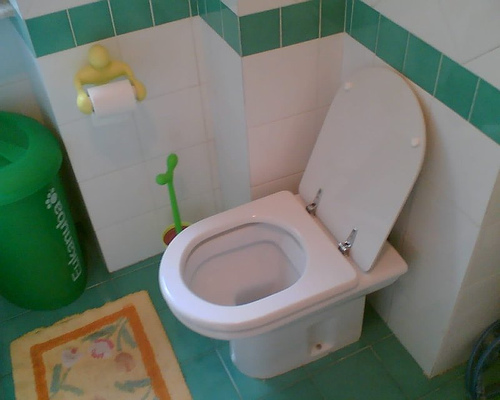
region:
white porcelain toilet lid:
[298, 59, 441, 309]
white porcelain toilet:
[148, 38, 448, 382]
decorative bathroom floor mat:
[2, 285, 184, 395]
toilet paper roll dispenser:
[51, 23, 173, 138]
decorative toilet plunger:
[142, 148, 209, 263]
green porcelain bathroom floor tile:
[293, 331, 400, 398]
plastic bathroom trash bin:
[0, 81, 80, 319]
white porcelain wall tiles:
[138, 25, 231, 138]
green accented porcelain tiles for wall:
[186, 0, 408, 62]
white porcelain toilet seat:
[151, 173, 351, 323]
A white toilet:
[156, 65, 428, 382]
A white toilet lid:
[296, 61, 431, 273]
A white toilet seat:
[156, 188, 361, 333]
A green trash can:
[2, 110, 91, 310]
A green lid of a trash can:
[3, 108, 65, 205]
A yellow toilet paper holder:
[72, 43, 146, 113]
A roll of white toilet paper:
[87, 78, 139, 118]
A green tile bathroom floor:
[1, 259, 424, 394]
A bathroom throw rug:
[6, 287, 202, 399]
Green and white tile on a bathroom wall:
[23, 4, 496, 378]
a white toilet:
[157, 66, 428, 378]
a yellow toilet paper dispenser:
[72, 44, 147, 113]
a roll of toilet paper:
[85, 78, 138, 128]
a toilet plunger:
[153, 152, 190, 247]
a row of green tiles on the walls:
[7, 0, 498, 143]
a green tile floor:
[0, 230, 499, 399]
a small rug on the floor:
[8, 290, 193, 399]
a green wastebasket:
[0, 110, 89, 312]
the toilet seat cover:
[297, 65, 427, 272]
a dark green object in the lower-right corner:
[465, 320, 497, 399]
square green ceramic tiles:
[25, 1, 498, 117]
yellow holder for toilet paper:
[75, 47, 146, 120]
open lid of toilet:
[299, 66, 426, 271]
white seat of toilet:
[155, 188, 356, 332]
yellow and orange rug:
[11, 289, 197, 399]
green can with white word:
[3, 110, 89, 310]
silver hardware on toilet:
[305, 191, 360, 254]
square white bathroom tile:
[135, 86, 207, 160]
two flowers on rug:
[85, 323, 135, 373]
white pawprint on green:
[43, 187, 60, 212]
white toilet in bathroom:
[125, 95, 435, 397]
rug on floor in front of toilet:
[10, 276, 401, 398]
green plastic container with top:
[4, 102, 124, 315]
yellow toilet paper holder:
[59, 31, 176, 148]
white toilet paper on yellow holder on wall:
[65, 45, 185, 145]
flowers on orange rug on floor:
[8, 320, 198, 395]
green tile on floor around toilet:
[132, 258, 443, 395]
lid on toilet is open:
[147, 60, 442, 327]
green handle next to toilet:
[145, 150, 330, 335]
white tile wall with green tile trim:
[196, 7, 498, 162]